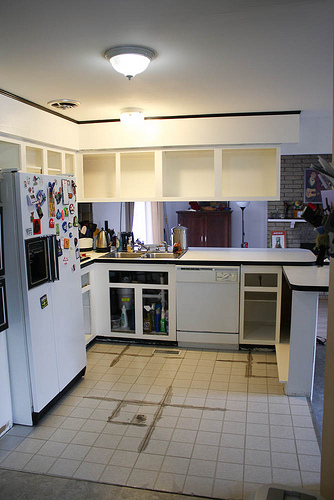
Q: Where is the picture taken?
A: Kitchen.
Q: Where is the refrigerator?
A: Left.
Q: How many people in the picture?
A: Zero.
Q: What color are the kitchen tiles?
A: White.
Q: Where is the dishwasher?
A: Under the counter.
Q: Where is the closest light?
A: Celing.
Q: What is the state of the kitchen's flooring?
A: Disrepair.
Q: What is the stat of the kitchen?
A: Clean.